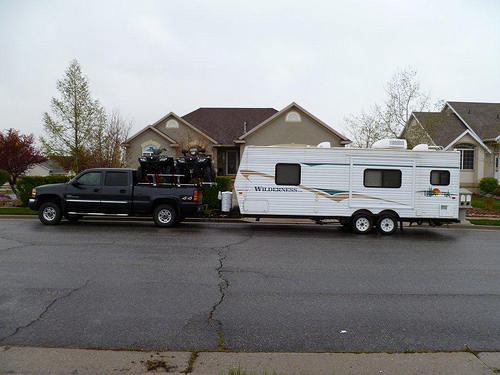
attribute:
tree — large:
[44, 55, 111, 187]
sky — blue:
[2, 0, 498, 165]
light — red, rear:
[191, 188, 200, 203]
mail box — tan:
[449, 176, 491, 244]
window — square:
[273, 161, 301, 186]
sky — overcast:
[1, 2, 497, 149]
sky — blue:
[28, 14, 489, 102]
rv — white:
[234, 138, 460, 233]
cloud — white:
[12, 63, 352, 143]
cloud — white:
[0, 0, 464, 90]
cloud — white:
[5, 0, 352, 140]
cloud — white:
[307, 19, 494, 147]